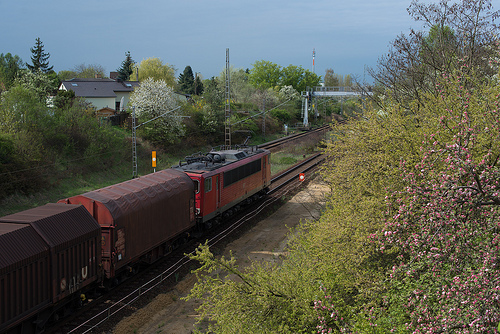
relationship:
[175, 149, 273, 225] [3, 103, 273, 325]
caboose of train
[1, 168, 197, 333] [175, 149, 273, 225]
last two cars before caboose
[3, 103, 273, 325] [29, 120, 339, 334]
train on tracks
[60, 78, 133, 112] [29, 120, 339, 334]
house near tracks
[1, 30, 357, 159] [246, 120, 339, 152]
bushes next to track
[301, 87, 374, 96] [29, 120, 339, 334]
bridge over train tracks